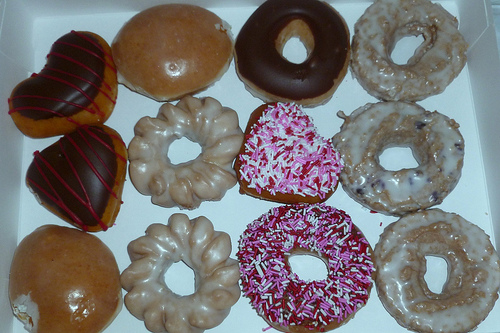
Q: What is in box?
A: Doughnuts.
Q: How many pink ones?
A: Two.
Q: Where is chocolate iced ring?
A: Top row.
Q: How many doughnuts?
A: 12.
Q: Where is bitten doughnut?
A: Bottom left.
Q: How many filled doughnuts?
A: Five.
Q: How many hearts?
A: Three.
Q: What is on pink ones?
A: Sprinkles.